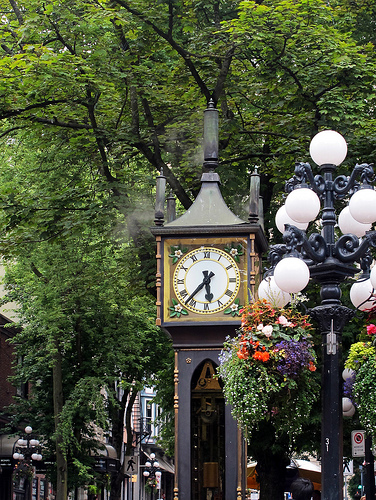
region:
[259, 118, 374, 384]
ornate street lamp with many orbs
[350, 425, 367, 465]
white rectangular street sign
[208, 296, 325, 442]
flowers in a hanging basket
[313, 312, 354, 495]
black metal lamppost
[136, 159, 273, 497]
metal grandfather clock in the park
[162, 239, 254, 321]
clock face reading 5:37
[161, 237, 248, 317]
clock face with four flowers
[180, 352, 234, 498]
chimes on a grandfather clock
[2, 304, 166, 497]
houses on a residential street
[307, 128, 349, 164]
orb on a street lamp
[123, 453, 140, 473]
walk symbol on white sign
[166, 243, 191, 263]
white flowers around clock face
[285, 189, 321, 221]
white globes on black pole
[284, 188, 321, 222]
globe next to pole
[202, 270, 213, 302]
black hour hand on clock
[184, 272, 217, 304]
black minute hand on clock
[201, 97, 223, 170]
tall gray finials on clock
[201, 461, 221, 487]
pendulum inside clock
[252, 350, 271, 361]
orange flowers hanging next to pole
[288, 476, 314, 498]
back of head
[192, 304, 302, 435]
the flowers are visible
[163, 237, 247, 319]
A clock face.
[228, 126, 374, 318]
Nine lights can be seen on the pole.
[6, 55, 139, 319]
Trees are in the background.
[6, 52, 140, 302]
The trees are green.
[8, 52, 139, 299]
The trees have a lot of leaves.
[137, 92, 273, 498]
A clock on a pedestal.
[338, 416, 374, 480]
A street sign.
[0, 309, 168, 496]
Buildings are in the background.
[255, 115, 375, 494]
The street lamp is black.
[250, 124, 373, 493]
The street lamp is metal.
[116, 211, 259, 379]
clock on top of the post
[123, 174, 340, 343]
clock on top of the post